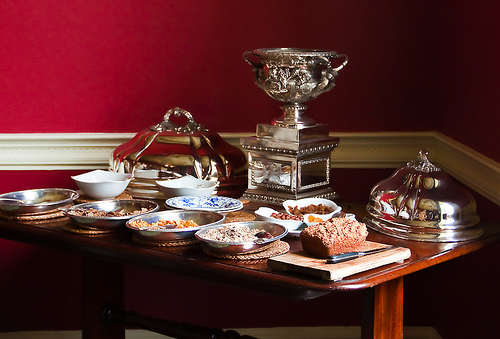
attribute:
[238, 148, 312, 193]
dot — silver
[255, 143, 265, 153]
dot — silver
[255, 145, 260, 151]
dot — silver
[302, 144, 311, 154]
dot — silver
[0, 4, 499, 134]
wall — red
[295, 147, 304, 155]
dot — silver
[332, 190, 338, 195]
dot — silver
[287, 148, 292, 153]
dot — silver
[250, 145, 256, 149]
dot — silver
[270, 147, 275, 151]
dot — silver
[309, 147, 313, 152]
dot — silver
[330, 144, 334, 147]
dot — silver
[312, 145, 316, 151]
dot — silver